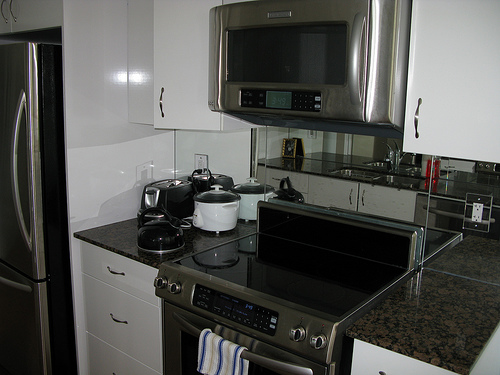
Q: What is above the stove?
A: Microwave.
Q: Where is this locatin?
A: Kitchen.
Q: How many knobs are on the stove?
A: Four.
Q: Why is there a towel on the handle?
A: To wipe with.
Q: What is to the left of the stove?
A: Refrigerator.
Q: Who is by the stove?
A: No one.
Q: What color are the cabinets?
A: White.